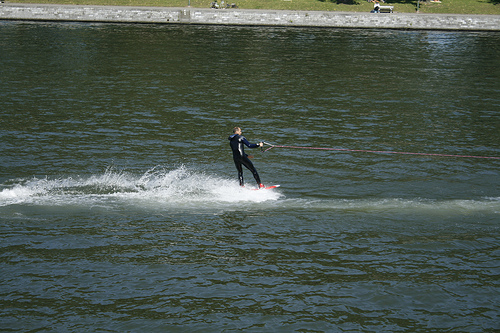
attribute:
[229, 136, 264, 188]
wet suit — shiny 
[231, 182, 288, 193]
ski — orange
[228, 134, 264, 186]
wetsuit — black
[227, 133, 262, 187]
wet suit — black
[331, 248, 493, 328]
ripples — small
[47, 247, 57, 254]
ripples — small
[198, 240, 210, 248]
ripples — small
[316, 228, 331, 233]
ripples — small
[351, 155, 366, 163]
ripples — small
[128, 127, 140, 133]
ripples — small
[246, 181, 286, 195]
board — red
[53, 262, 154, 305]
ripples — small